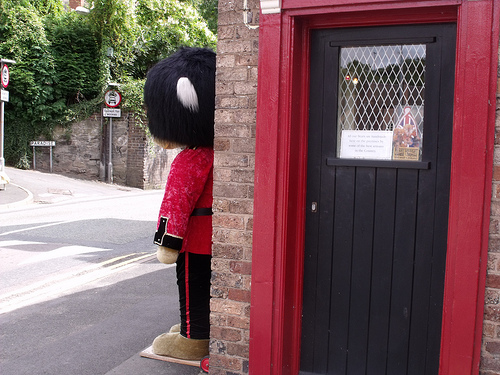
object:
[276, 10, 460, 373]
door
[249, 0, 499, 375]
door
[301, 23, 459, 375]
door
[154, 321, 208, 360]
feet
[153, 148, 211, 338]
clothes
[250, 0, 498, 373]
frame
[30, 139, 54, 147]
sign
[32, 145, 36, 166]
pole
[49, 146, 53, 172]
pole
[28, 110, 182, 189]
wall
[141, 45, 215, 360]
creature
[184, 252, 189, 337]
stripe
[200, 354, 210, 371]
wheel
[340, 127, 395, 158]
notice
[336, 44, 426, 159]
window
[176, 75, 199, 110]
fur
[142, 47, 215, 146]
helmet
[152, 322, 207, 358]
slippers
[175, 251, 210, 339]
pants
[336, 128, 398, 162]
paper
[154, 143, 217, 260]
jacket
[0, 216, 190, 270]
shadow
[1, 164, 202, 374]
cement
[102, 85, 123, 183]
sign